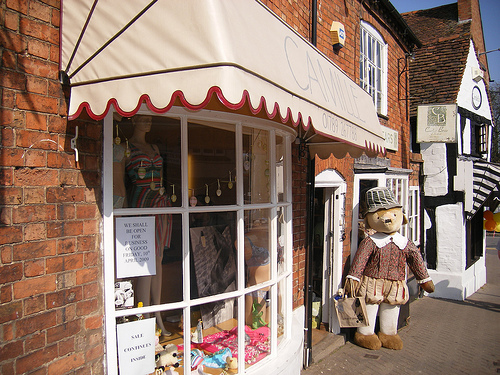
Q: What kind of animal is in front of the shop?
A: A bear.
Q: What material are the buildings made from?
A: Brick.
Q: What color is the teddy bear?
A: Brown.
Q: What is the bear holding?
A: A bag.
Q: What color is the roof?
A: Red.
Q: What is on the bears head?
A: A hat.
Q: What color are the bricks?
A: Red.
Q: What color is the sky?
A: Blue.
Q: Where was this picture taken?
A: Outside a store.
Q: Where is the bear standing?
A: On sidewalk.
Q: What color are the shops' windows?
A: White.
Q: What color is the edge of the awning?
A: Red.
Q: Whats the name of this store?
A: Camille.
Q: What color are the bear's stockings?
A: White.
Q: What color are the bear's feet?
A: Brown.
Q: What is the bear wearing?
A: Pantaloons.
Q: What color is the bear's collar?
A: White.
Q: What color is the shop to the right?
A: White.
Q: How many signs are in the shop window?
A: Two.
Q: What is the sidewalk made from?
A: Gray brick.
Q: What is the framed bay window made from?
A: Wooden white.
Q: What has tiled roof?
A: White building.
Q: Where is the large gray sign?
A: On the front of the building.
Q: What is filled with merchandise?
A: Charming window shop.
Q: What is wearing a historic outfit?
A: Large teddy bear.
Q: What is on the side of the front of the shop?
A: Scalloped edge of awning.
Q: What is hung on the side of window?
A: Signs.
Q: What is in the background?
A: Building with black and white facade.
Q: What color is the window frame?
A: White.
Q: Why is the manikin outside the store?
A: To catch attention.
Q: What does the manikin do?
A: It draws people to the store.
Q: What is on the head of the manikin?
A: A hat.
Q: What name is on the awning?
A: Camille.